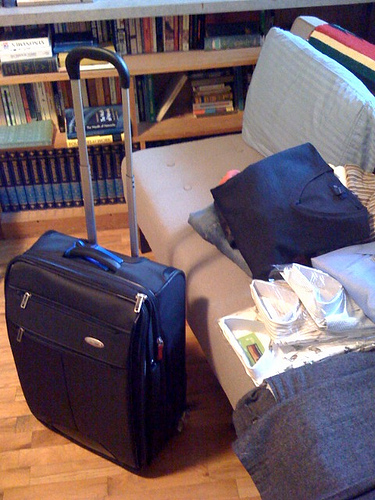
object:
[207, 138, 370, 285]
sweater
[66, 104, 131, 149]
books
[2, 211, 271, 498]
ground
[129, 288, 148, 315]
zip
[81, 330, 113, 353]
bag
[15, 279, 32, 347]
zips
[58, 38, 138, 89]
part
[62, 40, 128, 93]
handle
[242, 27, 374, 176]
pillow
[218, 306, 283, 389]
collar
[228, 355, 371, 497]
pants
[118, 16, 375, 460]
couch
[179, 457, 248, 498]
floor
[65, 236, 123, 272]
tag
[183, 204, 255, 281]
pillowcase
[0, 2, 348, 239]
bookshelf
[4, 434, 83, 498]
flooring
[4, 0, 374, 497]
room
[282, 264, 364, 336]
shirt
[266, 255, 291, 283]
bag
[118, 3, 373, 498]
right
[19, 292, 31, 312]
zipper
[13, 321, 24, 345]
zipper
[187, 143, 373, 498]
clothes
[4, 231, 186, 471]
bag